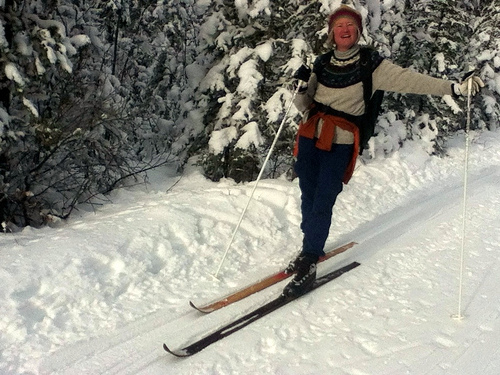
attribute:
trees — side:
[13, 55, 87, 216]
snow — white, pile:
[202, 59, 264, 88]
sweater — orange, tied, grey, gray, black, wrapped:
[325, 127, 337, 134]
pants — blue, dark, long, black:
[296, 157, 349, 250]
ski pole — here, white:
[447, 71, 479, 322]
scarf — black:
[307, 57, 358, 80]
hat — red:
[323, 3, 360, 15]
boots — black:
[290, 256, 329, 286]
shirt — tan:
[304, 84, 361, 112]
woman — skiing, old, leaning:
[260, 8, 426, 296]